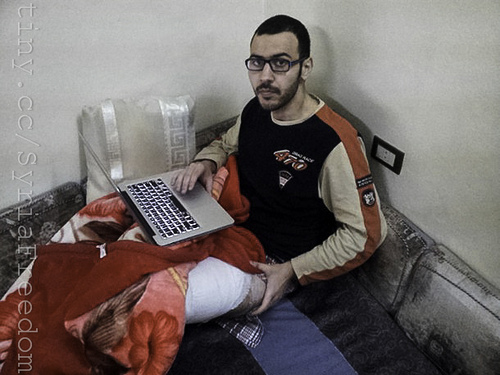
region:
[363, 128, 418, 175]
a white and black outlet on the wall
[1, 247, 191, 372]
red bedspread with floral patterns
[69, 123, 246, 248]
a laptop on man's lap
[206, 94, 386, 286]
man wearing a long sleeve shirt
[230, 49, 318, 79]
man wearing black glasses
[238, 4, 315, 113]
man with short hair and short beard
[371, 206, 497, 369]
silvery cushions against the wall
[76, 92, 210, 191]
a white cushion propped against the wall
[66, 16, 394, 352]
man sitting on a bed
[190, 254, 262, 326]
white bandage wrapped around man's knee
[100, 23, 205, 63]
solid white color on wall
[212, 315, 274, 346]
plaid color on blanket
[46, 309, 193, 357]
large red flower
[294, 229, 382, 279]
wrinkles in man's shirt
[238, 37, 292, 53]
wrinkles in man's forehead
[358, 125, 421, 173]
small black and white outlet on wall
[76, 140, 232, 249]
silver lap top on man's lap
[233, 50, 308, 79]
black glasses on man's face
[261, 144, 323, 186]
red logo on black shirt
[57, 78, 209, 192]
silver pillow against wall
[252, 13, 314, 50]
The man has black hair.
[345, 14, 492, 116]
The color of the wall is white.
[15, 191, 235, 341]
The print of the blanket is floral.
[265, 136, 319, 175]
The numbers on the shirt is 470.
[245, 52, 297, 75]
The man is wearing glasses.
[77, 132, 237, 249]
The man is holding a laptop.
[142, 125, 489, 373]
The man is sitting on a couch.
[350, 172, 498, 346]
There are two pillows visible.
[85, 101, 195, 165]
The color of this pillow is white.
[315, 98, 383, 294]
The color of the stripe is orange.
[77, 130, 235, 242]
an open silver laptop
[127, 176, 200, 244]
keyboard on laptop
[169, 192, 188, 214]
black spacebar on keyboard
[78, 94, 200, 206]
square ivory colored pillow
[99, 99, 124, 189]
satin strip on ivory pillow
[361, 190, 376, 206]
patch on sleeve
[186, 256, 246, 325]
white gauze bandage around leg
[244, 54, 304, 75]
man wearing black glasses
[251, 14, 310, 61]
man has short black hair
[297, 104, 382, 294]
orange stripe on sleeve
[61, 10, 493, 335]
a man on a couch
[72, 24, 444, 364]
a man on a bed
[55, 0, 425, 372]
a man on a laptop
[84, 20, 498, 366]
a man wearing glasses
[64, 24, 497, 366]
a man with a blanket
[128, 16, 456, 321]
a man with a mustache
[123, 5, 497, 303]
a man with short hair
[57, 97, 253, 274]
a silver and black laptop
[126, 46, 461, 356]
a man wearing a black and orange shirt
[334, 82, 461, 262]
an electric plug